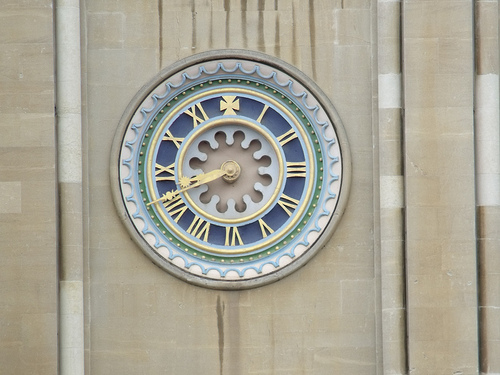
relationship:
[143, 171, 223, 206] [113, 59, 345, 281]
hands of clock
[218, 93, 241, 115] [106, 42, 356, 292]
cross on clock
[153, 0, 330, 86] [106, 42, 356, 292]
stains on clock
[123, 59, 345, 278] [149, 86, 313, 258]
decoration around clock face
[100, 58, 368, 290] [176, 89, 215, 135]
clock has roman numeral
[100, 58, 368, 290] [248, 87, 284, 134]
clock has roman numeral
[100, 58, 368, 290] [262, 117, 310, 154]
clock has roman numeral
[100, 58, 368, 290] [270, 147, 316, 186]
clock has roman numeral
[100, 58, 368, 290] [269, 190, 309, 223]
clock has roman numeral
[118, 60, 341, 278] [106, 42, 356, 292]
design on clock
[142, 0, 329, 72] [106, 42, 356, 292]
wavy design above clock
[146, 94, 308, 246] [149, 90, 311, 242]
blue under numbers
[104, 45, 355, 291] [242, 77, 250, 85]
circle with dot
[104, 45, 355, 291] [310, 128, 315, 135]
circle with dot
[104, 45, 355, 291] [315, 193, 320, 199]
circle with dot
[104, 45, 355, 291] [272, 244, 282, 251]
circle with dot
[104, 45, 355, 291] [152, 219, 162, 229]
circle with dot